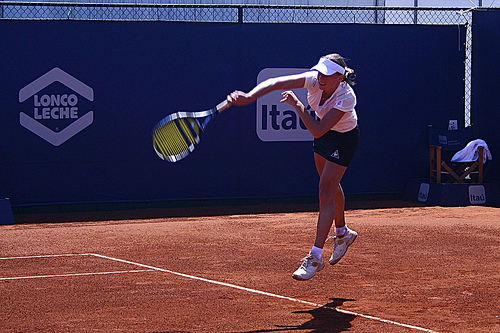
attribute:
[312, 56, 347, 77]
visor — white, small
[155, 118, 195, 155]
net — yellow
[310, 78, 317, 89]
logo — white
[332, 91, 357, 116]
sleeve — long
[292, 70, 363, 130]
tee — white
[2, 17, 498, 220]
wall — blue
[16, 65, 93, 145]
logo — white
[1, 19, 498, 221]
barrier — blue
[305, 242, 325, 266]
sock — white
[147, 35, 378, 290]
woman — playing tennis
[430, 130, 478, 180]
chair — blue, white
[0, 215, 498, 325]
tennis courts — dirt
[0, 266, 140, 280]
line — white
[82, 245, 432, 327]
line — white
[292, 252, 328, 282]
shoe — white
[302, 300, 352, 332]
shadow — black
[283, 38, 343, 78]
visor — white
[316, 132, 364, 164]
shorts — navy blue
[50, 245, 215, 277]
lines — white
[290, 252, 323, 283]
shoe — dirty, white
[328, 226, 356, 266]
shoe — dirty, white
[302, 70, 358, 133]
shirt — white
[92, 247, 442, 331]
line — white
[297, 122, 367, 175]
skirt — black